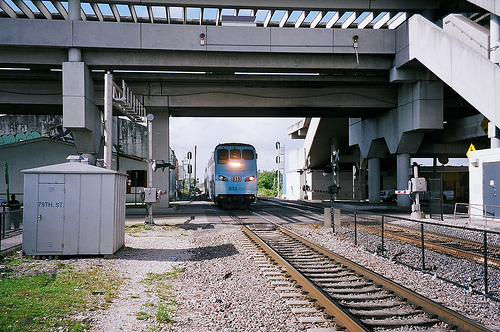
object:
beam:
[293, 11, 311, 29]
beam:
[278, 9, 293, 28]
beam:
[262, 10, 276, 28]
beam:
[181, 6, 186, 24]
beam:
[164, 6, 170, 25]